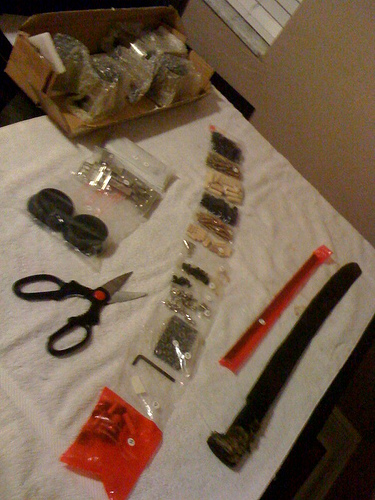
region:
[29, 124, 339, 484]
items packaged for sale on a table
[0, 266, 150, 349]
black and silver kitchen scissors on table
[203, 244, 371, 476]
knife on table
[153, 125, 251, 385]
small beads in clear plastic bags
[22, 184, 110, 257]
sunglasses on table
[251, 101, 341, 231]
white cloth on table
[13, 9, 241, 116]
groups of small items in baggies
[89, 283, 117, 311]
red dot on the scissors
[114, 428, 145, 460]
bags has a number on it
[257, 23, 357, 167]
floor is multi-colored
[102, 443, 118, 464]
part of a polythene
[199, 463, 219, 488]
part of a towel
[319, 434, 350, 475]
part of a carpet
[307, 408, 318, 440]
edge of a table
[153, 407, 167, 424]
edge of a bag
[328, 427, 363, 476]
pat of a floor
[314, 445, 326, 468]
edge of a carpet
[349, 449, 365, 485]
pat of a floor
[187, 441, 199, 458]
part of a towwel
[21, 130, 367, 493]
some tools laid out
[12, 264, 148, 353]
black and red scissors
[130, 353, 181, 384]
an L wrench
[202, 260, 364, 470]
a long knife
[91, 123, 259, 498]
little packets of parts and pieces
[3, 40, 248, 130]
a cardboard box filled with wrapped items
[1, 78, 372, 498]
a white towel under all the tools laid out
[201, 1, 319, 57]
part of a window blind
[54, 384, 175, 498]
the last part packet is red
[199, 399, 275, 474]
the handle of this knife is messed up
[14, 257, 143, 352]
Scissors on a table.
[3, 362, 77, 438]
Towel over the table.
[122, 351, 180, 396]
Small brown furniture tool.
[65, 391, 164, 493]
Red bag with screws.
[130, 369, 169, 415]
Stickers on the bag.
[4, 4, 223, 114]
Open box on the table.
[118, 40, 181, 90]
Bubble wrap in the box.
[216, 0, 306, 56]
Blind over the window.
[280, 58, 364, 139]
The wall is beige.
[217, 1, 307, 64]
The blinds are closed.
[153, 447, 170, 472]
the towel is white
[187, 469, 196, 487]
the towel is white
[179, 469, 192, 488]
the towel is white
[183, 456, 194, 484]
the towel is white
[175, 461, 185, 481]
the towel is white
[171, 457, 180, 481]
the towel is white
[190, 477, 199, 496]
the towel is white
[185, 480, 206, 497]
the towel is white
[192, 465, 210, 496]
the towel is white